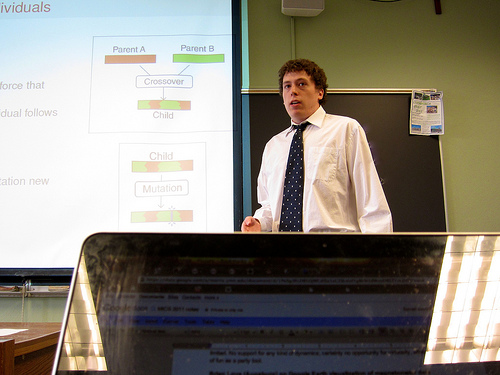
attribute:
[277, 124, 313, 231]
tie — blue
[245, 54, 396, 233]
man — brown haired, curly haired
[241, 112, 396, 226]
shirt — white, long sleeve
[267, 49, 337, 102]
hair — brown, curly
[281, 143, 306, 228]
tie — dotted, black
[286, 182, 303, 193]
dots — white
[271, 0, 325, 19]
speaker box — white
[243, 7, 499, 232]
wall — green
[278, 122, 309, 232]
tie — polka dot, white, blue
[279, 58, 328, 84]
afro — jewish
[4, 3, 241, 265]
screen — white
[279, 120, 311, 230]
spots — white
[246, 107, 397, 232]
shirt — long sleeved, white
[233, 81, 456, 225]
blackboard — empty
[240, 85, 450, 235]
chalkboard — black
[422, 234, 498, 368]
light — white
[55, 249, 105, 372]
light — white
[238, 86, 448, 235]
board — black